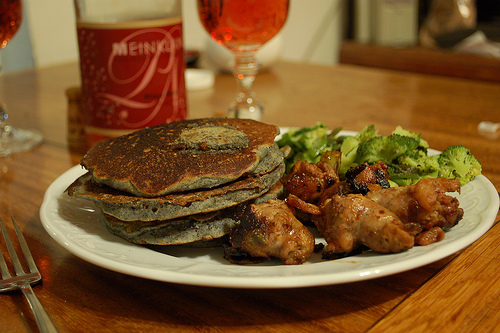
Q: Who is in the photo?
A: No one.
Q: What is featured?
A: Food.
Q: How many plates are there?
A: One.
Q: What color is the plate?
A: White.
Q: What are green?
A: Vegetables.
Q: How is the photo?
A: Clear.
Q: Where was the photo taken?
A: Near food.